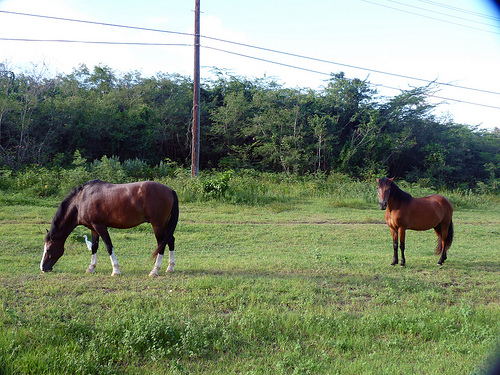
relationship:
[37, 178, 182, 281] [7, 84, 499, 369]
horse in field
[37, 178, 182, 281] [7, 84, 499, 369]
horse standing in field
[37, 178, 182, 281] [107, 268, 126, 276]
horse has foot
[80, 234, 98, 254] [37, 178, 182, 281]
bird behind horse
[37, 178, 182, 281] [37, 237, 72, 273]
horse has face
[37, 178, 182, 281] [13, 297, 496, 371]
horse standing on grass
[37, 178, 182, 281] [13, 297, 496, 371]
horse eating grass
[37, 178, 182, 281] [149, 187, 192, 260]
horse has tail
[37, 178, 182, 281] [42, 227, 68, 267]
horse has head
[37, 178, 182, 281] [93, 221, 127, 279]
horse has left front foot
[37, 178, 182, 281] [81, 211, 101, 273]
horse has right front foot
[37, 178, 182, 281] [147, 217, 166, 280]
horse has left back leg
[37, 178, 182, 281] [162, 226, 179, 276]
horse has right back leg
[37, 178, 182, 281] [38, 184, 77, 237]
horse has mane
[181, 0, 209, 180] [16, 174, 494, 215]
pole in ground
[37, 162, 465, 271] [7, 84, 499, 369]
two horses are in field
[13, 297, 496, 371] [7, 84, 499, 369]
grass in field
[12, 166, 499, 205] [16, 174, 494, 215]
bushes are on ground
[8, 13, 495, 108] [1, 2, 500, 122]
telephone wires are in sky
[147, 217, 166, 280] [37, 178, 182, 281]
left back leg of horse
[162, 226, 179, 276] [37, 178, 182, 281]
right back leg of horse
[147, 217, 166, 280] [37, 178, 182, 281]
left back leg of a horse